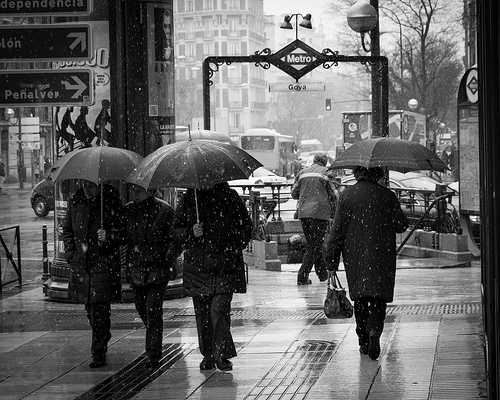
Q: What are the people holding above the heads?
A: Umbrellas.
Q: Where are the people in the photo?
A: City sidewalk.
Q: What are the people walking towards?
A: The metro.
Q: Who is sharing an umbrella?
A: Two people.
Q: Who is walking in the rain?
A: Five people.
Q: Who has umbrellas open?
A: The people.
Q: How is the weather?
A: It is raining.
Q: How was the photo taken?
A: In black and white.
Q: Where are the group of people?
A: Walking in the rain.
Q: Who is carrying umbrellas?
A: A group of people.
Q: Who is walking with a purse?
A: A woman.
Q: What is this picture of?
A: A city street on a rainy day.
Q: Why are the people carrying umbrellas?
A: It is raining.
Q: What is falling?
A: Rain.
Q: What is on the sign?
A: Metro.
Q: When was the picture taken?
A: Daytime.